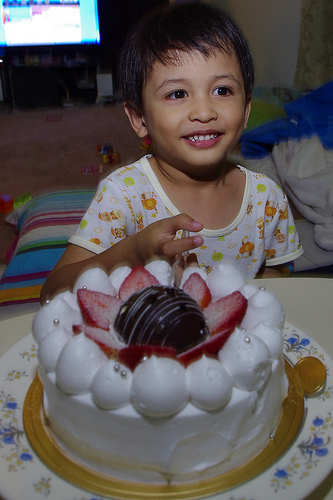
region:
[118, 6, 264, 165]
A small childs face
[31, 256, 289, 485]
A starberry white cake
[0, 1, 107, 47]
An LCD TV screen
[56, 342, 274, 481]
Icing on a birthday cake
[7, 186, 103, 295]
A multi colored pillow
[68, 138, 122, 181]
Childs toys on floor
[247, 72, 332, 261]
Assorted linens and bedding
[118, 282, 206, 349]
A chocolate candy sphere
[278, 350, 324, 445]
Faux gold plastic plate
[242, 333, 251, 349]
Silver cake frost icing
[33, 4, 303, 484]
A little boy and a delicious looking cake.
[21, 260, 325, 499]
The cake is on top of a yellow cake tray.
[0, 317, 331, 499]
The yellow cake tray on a white floral plate.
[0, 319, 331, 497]
Small blue flowers and yellow flowers on the plate.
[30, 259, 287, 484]
The cake is covered in fluffy white frosting.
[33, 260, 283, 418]
White puffs of frosting on top of the cake.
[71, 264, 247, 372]
Large strawberries cut in half to form flower pedals.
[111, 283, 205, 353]
Large ball of chocholate in the center of the cake.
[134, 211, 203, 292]
A clear knife in the child's hand.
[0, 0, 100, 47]
A bright television screen behind the boy.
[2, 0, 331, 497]
Little boy cutting cake.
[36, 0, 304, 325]
Little boy with brown hair.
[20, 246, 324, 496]
Cake with white icing.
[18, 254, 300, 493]
White cake with strawberries on top.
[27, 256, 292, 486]
Cake with vanilla icing with small grey beads on top.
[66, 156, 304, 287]
Orange designs on small white t-shirt.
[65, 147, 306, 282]
Green designs on small white t-shirt.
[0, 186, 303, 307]
Multi-colored pillow behind little boy.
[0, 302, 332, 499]
Cake sitting on multi-color plate.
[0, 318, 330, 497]
Cake sitting on round cake.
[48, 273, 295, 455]
A cake on the table.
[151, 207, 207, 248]
The little boy is holding a knife.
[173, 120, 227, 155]
The child is smiling.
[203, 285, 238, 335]
Strawberries on the cake.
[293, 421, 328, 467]
the plate have blue flowers on the edge.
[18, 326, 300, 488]
A cake sitting on top of the plate.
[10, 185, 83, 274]
A pillow on the floor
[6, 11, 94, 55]
The television is on.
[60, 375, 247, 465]
the cake is white.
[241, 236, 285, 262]
The shirt have mushrooms on it.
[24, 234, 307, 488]
this is a cake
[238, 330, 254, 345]
the balls are silver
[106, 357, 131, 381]
this silver balls are edible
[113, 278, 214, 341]
a chocolate dome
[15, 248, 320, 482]
there is white frosting on the cake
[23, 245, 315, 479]
the cake is a circle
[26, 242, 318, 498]
the cake is round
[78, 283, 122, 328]
this is a strawberry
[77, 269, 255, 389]
the strawberries are cut in half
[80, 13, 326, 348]
she is cutting into the cake with a plastic knife